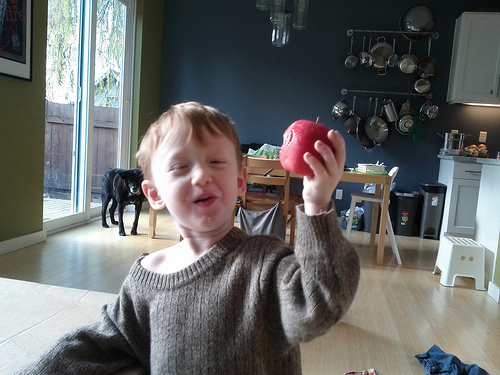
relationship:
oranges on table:
[440, 132, 499, 172] [359, 151, 415, 226]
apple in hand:
[284, 108, 336, 188] [312, 161, 357, 212]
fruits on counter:
[246, 145, 280, 173] [434, 134, 497, 194]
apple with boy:
[284, 108, 336, 188] [116, 115, 350, 365]